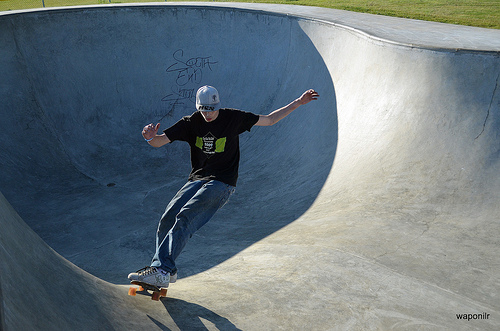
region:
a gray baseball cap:
[193, 84, 222, 112]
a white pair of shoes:
[126, 266, 180, 288]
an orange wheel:
[126, 283, 138, 298]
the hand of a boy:
[298, 84, 323, 108]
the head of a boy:
[194, 83, 221, 124]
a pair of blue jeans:
[146, 175, 238, 270]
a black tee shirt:
[162, 105, 264, 187]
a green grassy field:
[0, 0, 499, 32]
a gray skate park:
[0, 0, 498, 329]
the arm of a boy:
[233, 85, 320, 140]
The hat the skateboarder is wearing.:
[195, 85, 217, 120]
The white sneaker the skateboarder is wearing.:
[125, 265, 165, 280]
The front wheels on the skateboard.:
[125, 282, 157, 302]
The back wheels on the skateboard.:
[140, 285, 170, 291]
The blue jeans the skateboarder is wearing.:
[151, 170, 237, 266]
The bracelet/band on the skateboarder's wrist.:
[140, 132, 155, 142]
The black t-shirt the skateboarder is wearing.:
[185, 115, 245, 176]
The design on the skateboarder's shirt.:
[193, 133, 228, 158]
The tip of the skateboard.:
[131, 274, 161, 291]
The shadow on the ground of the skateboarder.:
[136, 288, 246, 330]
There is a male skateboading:
[55, 37, 413, 294]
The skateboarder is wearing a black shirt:
[107, 71, 342, 323]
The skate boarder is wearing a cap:
[141, 86, 271, 166]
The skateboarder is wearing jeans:
[122, 72, 332, 328]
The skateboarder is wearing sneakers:
[107, 74, 257, 328]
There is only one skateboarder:
[67, 66, 327, 327]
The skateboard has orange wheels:
[93, 211, 244, 311]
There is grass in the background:
[44, 3, 494, 95]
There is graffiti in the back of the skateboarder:
[80, 39, 352, 316]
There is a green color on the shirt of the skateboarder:
[100, 58, 287, 320]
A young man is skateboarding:
[113, 67, 335, 309]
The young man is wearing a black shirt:
[124, 85, 296, 200]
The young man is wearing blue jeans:
[138, 160, 255, 278]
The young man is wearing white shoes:
[123, 251, 203, 306]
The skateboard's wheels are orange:
[103, 265, 184, 309]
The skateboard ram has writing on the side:
[138, 43, 256, 131]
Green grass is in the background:
[293, 2, 498, 27]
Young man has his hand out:
[231, 71, 337, 161]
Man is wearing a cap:
[180, 76, 243, 131]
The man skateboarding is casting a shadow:
[129, 279, 295, 329]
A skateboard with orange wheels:
[124, 254, 180, 305]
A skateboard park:
[17, 27, 477, 320]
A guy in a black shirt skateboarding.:
[126, 92, 269, 303]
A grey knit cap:
[191, 80, 228, 112]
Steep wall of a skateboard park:
[362, 48, 394, 266]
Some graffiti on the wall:
[146, 36, 219, 132]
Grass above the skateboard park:
[401, 0, 488, 18]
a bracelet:
[142, 134, 160, 145]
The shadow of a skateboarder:
[168, 300, 237, 322]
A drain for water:
[100, 177, 122, 195]